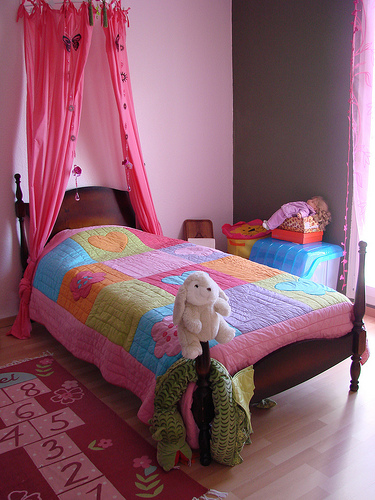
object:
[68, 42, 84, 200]
adornment string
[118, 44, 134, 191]
adornment string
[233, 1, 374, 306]
pink wall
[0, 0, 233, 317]
pink wall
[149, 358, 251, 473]
dragon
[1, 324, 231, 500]
floorboards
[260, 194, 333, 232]
toy doll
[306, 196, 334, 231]
brown hair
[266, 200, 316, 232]
pink clothes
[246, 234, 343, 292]
container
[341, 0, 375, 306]
pink drapes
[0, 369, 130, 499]
hopscotch pattern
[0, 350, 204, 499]
rug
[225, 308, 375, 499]
floorboards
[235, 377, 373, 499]
floor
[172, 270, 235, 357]
stuffed bunny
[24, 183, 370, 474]
bed